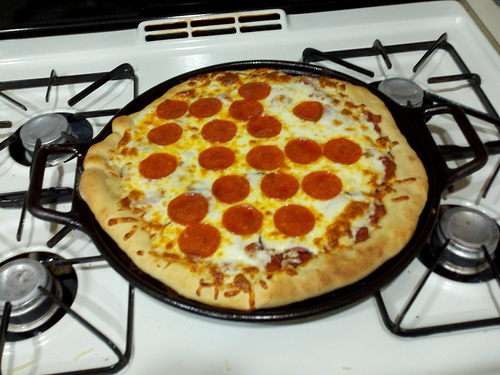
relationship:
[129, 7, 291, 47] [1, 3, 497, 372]
oven vent on oven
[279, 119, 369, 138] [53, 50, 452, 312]
cheese on pizza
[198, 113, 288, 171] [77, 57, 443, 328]
toppings on pizza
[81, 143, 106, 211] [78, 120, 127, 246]
puffy on crust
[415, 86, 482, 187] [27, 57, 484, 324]
handle on pan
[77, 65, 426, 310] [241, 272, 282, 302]
pizza seen part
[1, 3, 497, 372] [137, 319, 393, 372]
oven seen part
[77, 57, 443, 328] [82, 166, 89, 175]
pizza has edge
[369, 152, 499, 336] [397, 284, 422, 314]
burner has part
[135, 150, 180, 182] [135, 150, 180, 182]
piece in piece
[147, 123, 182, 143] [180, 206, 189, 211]
pepperoni in piece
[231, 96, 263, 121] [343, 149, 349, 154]
pepperoni in piece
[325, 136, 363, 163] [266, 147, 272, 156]
pepperoni in piece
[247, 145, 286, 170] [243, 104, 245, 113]
pepperoni in piece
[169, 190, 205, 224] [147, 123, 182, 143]
pepperoni in pepperoni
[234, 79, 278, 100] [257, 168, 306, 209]
piece in piece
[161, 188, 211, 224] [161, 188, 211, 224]
piece in piece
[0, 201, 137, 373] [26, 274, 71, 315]
burner seen part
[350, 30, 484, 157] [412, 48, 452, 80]
burner seen part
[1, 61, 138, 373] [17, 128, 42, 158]
burner seen part